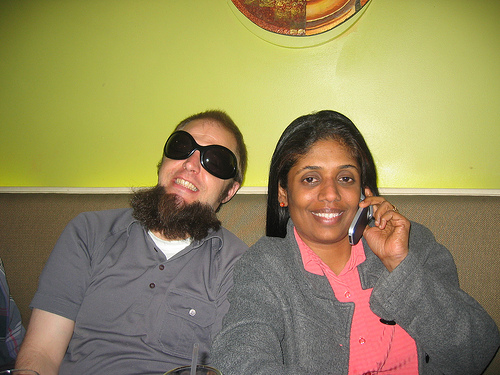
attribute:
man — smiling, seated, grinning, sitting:
[13, 104, 254, 375]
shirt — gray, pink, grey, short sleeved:
[28, 196, 249, 375]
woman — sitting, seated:
[205, 106, 499, 375]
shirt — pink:
[294, 221, 420, 373]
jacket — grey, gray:
[209, 203, 498, 374]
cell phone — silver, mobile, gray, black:
[346, 186, 375, 246]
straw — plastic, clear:
[189, 340, 206, 371]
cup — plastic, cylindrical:
[153, 360, 220, 374]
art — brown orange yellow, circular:
[228, 1, 375, 37]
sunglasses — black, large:
[158, 129, 241, 186]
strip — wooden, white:
[0, 186, 499, 198]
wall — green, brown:
[3, 3, 499, 340]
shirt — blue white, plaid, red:
[0, 260, 29, 365]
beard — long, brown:
[127, 184, 223, 238]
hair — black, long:
[265, 105, 387, 242]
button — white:
[184, 305, 199, 322]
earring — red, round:
[279, 199, 287, 207]